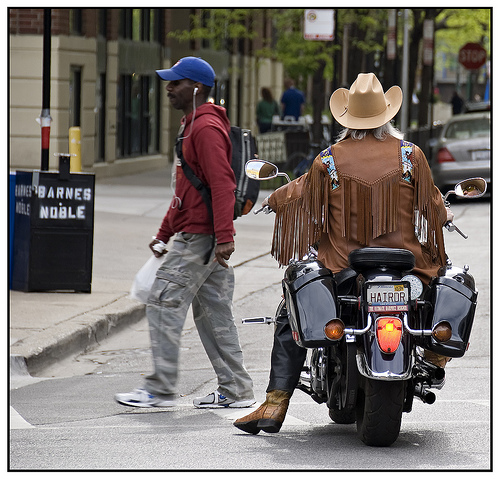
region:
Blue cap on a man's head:
[150, 53, 216, 85]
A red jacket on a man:
[146, 100, 233, 240]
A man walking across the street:
[111, 52, 256, 407]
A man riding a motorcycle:
[231, 70, 467, 440]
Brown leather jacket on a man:
[260, 130, 450, 276]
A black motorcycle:
[237, 150, 487, 442]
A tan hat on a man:
[326, 70, 401, 130]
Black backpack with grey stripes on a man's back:
[170, 120, 262, 219]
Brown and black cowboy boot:
[229, 388, 302, 438]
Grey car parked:
[426, 111, 490, 202]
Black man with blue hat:
[159, 41, 221, 117]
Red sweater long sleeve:
[168, 109, 242, 247]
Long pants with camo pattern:
[143, 216, 256, 408]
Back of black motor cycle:
[286, 244, 456, 410]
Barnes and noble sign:
[26, 167, 96, 296]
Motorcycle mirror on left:
[236, 139, 296, 214]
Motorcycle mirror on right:
[438, 166, 492, 235]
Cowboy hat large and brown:
[305, 66, 450, 175]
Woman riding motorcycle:
[258, 85, 473, 414]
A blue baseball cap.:
[155, 50, 227, 85]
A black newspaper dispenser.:
[15, 151, 102, 296]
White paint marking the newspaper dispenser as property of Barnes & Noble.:
[37, 183, 92, 228]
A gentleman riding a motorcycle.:
[258, 77, 476, 433]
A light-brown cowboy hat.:
[320, 63, 405, 128]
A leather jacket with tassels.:
[268, 127, 469, 268]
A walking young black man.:
[123, 53, 253, 410]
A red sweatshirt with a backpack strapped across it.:
[162, 108, 257, 237]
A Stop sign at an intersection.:
[452, 36, 494, 69]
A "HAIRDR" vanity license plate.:
[362, 286, 414, 310]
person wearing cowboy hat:
[318, 72, 439, 152]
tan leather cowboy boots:
[230, 382, 300, 457]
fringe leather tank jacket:
[273, 146, 463, 263]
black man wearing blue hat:
[138, 60, 240, 265]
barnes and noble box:
[18, 145, 95, 302]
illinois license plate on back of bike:
[352, 277, 412, 314]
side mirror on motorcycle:
[447, 172, 479, 222]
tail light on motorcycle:
[357, 310, 407, 386]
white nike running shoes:
[112, 380, 180, 414]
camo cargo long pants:
[125, 204, 248, 407]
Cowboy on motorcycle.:
[273, 52, 415, 161]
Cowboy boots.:
[223, 343, 310, 469]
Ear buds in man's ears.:
[149, 75, 269, 188]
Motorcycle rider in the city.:
[221, 90, 436, 415]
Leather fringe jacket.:
[250, 150, 386, 236]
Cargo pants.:
[102, 187, 242, 442]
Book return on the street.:
[18, 132, 197, 364]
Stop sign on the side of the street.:
[446, 18, 498, 80]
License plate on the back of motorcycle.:
[306, 195, 447, 325]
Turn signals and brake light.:
[306, 307, 486, 350]